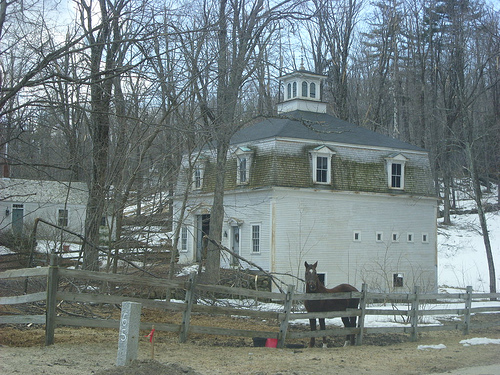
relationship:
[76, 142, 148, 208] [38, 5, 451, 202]
branch of tree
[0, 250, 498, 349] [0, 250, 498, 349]
fence has fence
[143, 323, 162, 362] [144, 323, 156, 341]
post has marker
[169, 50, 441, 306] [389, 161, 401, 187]
building with window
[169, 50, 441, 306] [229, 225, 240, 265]
building with door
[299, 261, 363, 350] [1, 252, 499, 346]
horse in front fence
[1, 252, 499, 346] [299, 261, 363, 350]
fence in front horse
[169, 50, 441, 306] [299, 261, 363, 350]
building behind horse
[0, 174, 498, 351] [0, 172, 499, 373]
snow on ground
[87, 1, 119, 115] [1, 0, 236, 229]
branch of tree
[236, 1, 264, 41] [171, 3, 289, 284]
branch of tree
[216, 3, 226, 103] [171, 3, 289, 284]
branch of tree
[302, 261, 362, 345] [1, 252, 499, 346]
horse is in fence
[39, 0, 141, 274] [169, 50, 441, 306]
tree is next to building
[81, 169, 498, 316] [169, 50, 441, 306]
snow is behind building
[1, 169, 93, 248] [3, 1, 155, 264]
building is behind trees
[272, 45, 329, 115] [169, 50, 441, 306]
steeple on top of building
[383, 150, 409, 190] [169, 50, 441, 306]
window in building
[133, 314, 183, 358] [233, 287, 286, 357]
flag on stick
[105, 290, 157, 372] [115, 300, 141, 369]
numbers on post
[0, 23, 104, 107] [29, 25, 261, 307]
branch of tree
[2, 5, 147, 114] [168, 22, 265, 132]
branch of tree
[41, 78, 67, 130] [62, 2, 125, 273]
branch of tree